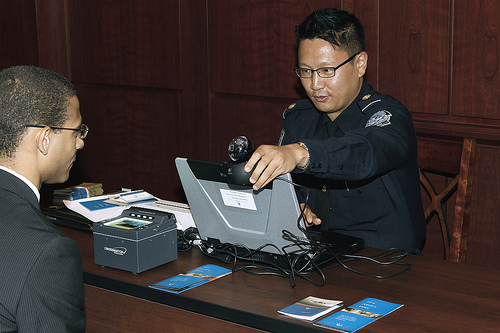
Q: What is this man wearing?
A: Business suit.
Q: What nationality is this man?
A: Asian.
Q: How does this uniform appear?
A: Navy blue in color.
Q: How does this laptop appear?
A: Black and silver in color.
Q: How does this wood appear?
A: Dark in color.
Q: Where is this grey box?
A: On the desk.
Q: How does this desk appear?
A: Wooden.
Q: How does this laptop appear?
A: GREY AND BLACK.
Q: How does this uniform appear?
A: Black.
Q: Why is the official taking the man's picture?
A: Identification.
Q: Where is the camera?
A: On the computer.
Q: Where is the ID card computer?
A: On the table.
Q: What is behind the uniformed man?
A: Chair.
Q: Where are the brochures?
A: On the table.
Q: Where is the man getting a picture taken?
A: In front of the table.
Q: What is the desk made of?
A: Wood.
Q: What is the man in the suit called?
A: Police officer.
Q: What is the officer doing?
A: Taking a photo.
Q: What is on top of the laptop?
A: Webcam.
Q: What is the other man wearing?
A: Suit.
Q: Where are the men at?
A: Office.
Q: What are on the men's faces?
A: Glasses.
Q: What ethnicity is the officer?
A: Asian.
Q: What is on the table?
A: Pamphlets.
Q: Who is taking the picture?
A: Police officer.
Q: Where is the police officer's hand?
A: On camera.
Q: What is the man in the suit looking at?
A: The camera.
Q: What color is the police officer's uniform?
A: Black.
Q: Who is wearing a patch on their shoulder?
A: Police officer.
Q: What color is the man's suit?
A: Black.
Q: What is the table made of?
A: Wood.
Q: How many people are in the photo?
A: Two.